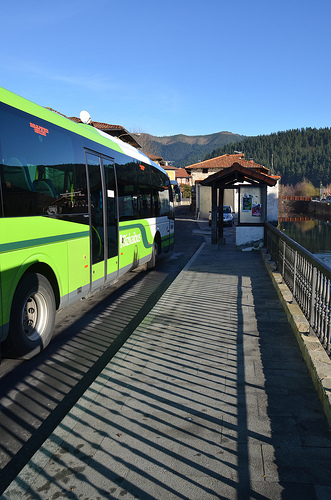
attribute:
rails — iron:
[250, 249, 330, 317]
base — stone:
[256, 270, 321, 346]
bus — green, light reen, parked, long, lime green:
[21, 123, 156, 267]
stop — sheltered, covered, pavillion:
[181, 170, 294, 269]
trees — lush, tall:
[249, 123, 314, 173]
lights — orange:
[26, 122, 99, 179]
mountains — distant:
[106, 109, 263, 211]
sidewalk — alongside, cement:
[124, 264, 252, 434]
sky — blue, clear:
[93, 43, 310, 118]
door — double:
[66, 133, 156, 281]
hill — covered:
[233, 138, 321, 184]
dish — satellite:
[65, 90, 129, 136]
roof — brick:
[174, 142, 280, 193]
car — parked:
[175, 192, 252, 232]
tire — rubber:
[3, 272, 90, 351]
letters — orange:
[6, 115, 100, 162]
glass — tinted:
[3, 163, 181, 217]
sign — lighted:
[6, 104, 186, 185]